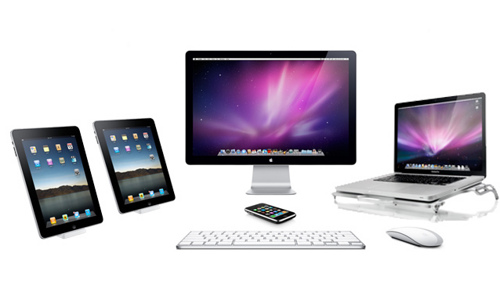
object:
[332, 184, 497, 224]
laptop stand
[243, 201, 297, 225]
apple iphone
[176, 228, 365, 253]
keyboard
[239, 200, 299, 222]
phone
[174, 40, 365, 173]
monitor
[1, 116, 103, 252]
tablet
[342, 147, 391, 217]
ground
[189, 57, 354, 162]
screen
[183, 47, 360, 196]
computer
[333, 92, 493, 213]
computer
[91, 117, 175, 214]
computer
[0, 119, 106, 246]
computer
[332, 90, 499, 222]
laptop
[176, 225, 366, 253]
device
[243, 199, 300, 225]
smartphone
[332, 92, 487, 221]
apple mac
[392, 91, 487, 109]
menubar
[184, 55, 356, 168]
screen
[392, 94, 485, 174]
screen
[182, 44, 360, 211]
computer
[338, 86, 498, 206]
computer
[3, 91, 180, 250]
tablets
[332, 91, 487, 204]
electronic device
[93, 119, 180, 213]
ipad tablet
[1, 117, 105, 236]
apple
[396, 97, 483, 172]
wallpaper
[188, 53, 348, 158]
wallpaper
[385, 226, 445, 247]
mouse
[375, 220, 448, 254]
mouse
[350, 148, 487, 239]
dock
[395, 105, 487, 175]
computer screen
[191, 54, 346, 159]
computer screen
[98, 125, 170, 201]
computer screen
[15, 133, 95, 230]
computer screen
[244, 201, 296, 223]
operating system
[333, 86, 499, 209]
laptop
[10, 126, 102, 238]
device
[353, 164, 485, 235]
stand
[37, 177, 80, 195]
mountain